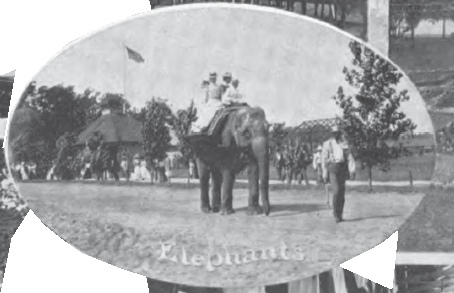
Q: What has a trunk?
A: Elephant.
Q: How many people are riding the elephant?
A: Four.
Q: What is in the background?
A: Trees.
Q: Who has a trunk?
A: Elephant.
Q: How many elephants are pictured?
A: One.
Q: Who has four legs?
A: The elephant.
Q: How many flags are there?
A: One.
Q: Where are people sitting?
A: On top of the elephant.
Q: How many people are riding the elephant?
A: Four.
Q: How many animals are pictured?
A: One.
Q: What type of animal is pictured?
A: Elephant.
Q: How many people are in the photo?
A: Six.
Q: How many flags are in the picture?
A: One.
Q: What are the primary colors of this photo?
A: Black, grey and white.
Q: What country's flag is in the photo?
A: United States of America.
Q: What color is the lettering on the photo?
A: White.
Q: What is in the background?
A: A building is in the background.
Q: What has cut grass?
A: An open field.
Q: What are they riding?
A: An elephant.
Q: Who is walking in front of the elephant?
A: A man.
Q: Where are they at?
A: The circus.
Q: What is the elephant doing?
A: Walking.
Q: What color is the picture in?
A: Black and white.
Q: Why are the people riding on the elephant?
A: For fun.